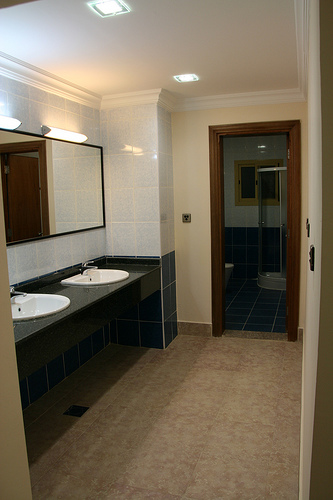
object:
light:
[93, 0, 125, 17]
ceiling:
[0, 0, 309, 101]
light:
[42, 125, 89, 143]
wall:
[0, 76, 180, 286]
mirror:
[0, 128, 105, 244]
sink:
[60, 264, 130, 286]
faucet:
[79, 261, 98, 276]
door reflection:
[5, 154, 44, 243]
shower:
[256, 167, 288, 288]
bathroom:
[0, 89, 332, 498]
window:
[241, 162, 278, 199]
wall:
[223, 141, 288, 229]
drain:
[63, 404, 90, 418]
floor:
[22, 333, 303, 498]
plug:
[182, 214, 191, 224]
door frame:
[209, 125, 224, 336]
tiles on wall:
[108, 253, 175, 353]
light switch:
[182, 213, 191, 223]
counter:
[6, 265, 162, 383]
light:
[2, 117, 22, 131]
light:
[176, 74, 198, 82]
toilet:
[225, 263, 234, 281]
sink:
[9, 292, 70, 323]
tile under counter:
[20, 324, 114, 411]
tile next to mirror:
[103, 110, 175, 256]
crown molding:
[97, 87, 174, 108]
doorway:
[208, 118, 301, 339]